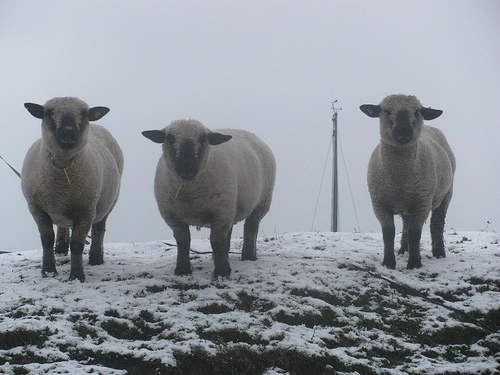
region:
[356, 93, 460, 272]
Lamb standing on snow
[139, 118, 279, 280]
Lamb standing on snow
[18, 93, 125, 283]
Lamb standing on snow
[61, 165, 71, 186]
Yellow tag on lamb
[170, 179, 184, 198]
Yellow tag on lamb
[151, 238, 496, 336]
Black cable along snow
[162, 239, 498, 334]
Black cable next to lamb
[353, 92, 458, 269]
Lamb next to black cable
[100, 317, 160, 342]
Patch of grass on snow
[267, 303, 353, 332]
Patch of grass on snow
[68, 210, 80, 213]
white fur on animal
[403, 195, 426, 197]
white fur on animal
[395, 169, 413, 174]
white fur on animal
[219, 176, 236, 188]
white fur on animal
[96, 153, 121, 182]
white fur on animal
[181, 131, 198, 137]
white fur on animal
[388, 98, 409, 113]
white fur on animal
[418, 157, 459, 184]
white fur on animal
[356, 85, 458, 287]
sheep standing to the right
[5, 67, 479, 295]
three adult sheep in white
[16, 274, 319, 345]
grass covered in snow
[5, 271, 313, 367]
snow on the ground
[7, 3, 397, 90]
dark and foggy sky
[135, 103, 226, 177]
sheep looking at camera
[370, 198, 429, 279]
sheep legs in the snow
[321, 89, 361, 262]
large pole behind sheep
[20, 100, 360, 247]
these are some sheep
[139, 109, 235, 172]
this is a head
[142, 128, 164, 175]
this is an ear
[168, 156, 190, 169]
this is a nose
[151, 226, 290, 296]
these are some legs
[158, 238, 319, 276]
the legs are short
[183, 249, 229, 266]
this is a hoof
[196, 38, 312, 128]
the sky is white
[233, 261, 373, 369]
there is snow on the ground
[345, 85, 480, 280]
a white sheep on snow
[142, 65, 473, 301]
two white sheep in winter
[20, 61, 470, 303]
three white sheep standing outside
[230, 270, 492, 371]
snow covering ground cover plants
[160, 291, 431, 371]
snowy plants on the ground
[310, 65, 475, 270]
pole behind a sheep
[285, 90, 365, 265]
pole in the distance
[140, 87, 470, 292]
a sheep with a raised head and lowered head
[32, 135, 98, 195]
sheep collar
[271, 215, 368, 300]
snow on the ground